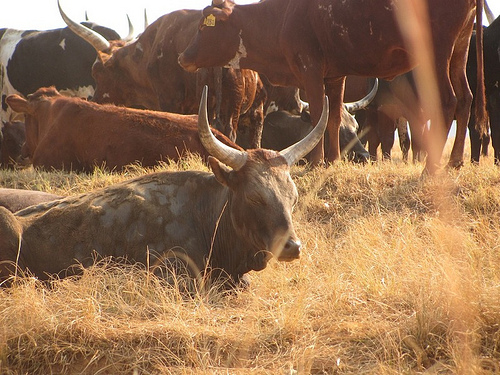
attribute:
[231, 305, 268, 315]
grass — part, tip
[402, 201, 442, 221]
plain — part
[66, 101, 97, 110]
body — part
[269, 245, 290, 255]
mouth — part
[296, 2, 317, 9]
back — part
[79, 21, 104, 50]
horn — part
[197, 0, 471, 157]
cow — brown, standing, laying, white, black, body